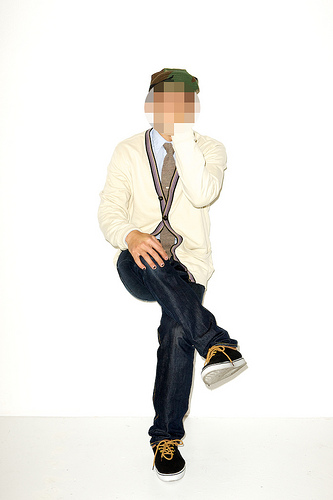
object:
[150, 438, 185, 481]
black sneakers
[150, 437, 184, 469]
laces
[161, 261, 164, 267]
nail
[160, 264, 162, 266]
polish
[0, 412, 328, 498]
floor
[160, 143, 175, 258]
hanging tie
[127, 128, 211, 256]
torso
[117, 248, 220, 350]
leg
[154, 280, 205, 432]
leg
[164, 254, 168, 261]
nails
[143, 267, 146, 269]
dark color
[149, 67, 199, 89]
hat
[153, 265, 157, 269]
nail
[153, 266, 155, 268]
polish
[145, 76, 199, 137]
face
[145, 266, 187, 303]
knee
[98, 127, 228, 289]
sweater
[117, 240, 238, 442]
jeans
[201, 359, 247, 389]
sneaker bottoms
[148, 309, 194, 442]
pant leg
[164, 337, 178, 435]
crease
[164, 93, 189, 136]
hand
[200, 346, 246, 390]
shoe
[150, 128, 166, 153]
collar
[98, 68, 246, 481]
man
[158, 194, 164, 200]
button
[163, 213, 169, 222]
button